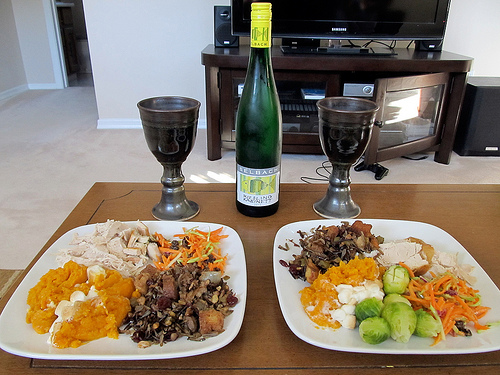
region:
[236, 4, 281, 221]
the green bottle on the table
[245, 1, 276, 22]
the yellow cap on the bottle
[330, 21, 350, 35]
the white logo on the television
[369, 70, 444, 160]
the open door to the cabinet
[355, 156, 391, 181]
the controller on the ground by the etertainment center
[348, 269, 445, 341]
round cabbage balls on the plate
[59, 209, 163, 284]
the white meat on the plate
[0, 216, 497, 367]
the food on the coffee table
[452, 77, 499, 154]
the black speaker on the ground near the TV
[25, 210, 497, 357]
Two meals on two plates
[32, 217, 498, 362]
Food on two plates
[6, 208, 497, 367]
Dinner for two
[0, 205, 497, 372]
Dinner on two white plates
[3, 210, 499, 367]
Two white plates on a table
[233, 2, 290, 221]
A bottle of wine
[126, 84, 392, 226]
Two wine glasses on a table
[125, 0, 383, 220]
Wine and wine glasses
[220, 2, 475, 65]
A television on a stand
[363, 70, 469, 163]
A door on a stande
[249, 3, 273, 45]
a yellow bottle neck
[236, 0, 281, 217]
a green wine bottle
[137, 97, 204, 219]
a brown metal goblet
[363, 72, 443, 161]
a glass and wood door on an entertainment center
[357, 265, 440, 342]
brussels sprouts on a plate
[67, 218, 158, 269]
chopped turkey on a white plate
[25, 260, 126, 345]
mashed sweet potatoes with marshmallows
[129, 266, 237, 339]
wild rice stuffing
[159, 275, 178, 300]
a piece of sausage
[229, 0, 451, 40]
a black flat screen television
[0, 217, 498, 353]
a couple of plates of food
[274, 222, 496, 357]
a plate of food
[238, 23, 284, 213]
a bottle of wine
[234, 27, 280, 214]
a green bottle of wine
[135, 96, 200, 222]
a metal goblet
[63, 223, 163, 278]
chicken brest on a plate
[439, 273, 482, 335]
carrots in a salad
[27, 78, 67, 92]
a white base board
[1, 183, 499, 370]
a brown wooden table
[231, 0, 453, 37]
a flat screen tv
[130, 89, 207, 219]
pewter goblet on the table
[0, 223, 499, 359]
two dinner plates on the table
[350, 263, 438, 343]
six brussels sprouts on the plate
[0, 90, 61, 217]
carpet is beige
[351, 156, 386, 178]
game controller on the floor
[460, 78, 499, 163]
black speaker on the floor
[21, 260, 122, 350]
mashed sweet potatoes on the plate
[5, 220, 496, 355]
white dinner plates are square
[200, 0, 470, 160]
entertainment center against the wall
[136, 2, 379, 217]
beverage bottle between two goblets